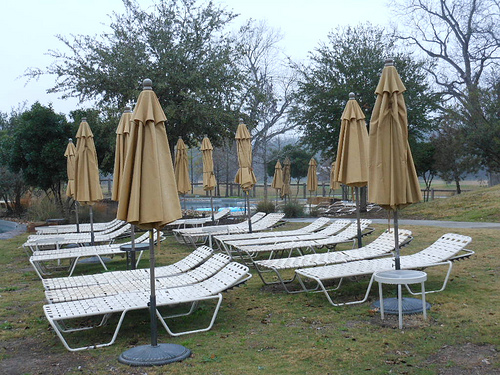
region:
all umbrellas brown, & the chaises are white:
[15, 41, 483, 373]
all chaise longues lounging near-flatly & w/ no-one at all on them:
[25, 204, 481, 331]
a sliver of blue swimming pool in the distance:
[194, 205, 259, 215]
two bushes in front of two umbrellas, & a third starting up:
[249, 199, 326, 219]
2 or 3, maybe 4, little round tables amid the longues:
[117, 223, 429, 332]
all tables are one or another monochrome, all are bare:
[113, 222, 434, 338]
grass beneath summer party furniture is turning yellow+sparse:
[0, 226, 498, 374]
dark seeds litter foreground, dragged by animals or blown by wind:
[0, 263, 498, 374]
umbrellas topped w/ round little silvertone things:
[58, 53, 416, 148]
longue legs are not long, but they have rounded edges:
[20, 205, 471, 360]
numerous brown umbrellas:
[32, 51, 447, 224]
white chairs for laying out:
[34, 203, 477, 330]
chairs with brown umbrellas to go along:
[21, 63, 458, 363]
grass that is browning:
[22, 227, 483, 364]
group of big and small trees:
[3, 13, 495, 215]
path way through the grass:
[221, 205, 492, 236]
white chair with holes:
[46, 281, 252, 321]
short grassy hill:
[365, 176, 498, 233]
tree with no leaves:
[411, 5, 498, 139]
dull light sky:
[11, 0, 493, 131]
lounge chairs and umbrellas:
[23, 54, 468, 361]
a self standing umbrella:
[119, 75, 188, 373]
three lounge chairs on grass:
[25, 242, 255, 356]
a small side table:
[368, 256, 438, 332]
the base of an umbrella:
[118, 332, 197, 370]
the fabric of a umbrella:
[112, 75, 182, 259]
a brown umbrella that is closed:
[115, 67, 183, 242]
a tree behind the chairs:
[45, 2, 281, 146]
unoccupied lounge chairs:
[30, 238, 254, 351]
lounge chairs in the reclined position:
[35, 241, 250, 356]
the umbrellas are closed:
[316, 52, 424, 252]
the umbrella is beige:
[349, 37, 426, 217]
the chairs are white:
[46, 245, 252, 330]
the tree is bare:
[419, 0, 488, 130]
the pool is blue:
[177, 166, 273, 218]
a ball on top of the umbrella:
[135, 75, 155, 92]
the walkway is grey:
[356, 180, 491, 236]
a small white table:
[362, 255, 434, 325]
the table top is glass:
[347, 256, 445, 334]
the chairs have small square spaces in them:
[2, 246, 278, 303]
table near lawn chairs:
[373, 266, 432, 336]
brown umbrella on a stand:
[124, 71, 189, 374]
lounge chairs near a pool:
[217, 226, 479, 301]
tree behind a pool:
[93, 1, 270, 218]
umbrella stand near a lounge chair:
[97, 296, 209, 365]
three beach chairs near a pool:
[29, 246, 255, 343]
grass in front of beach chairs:
[224, 312, 311, 361]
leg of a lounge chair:
[47, 318, 131, 353]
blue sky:
[282, 11, 319, 61]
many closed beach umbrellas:
[19, 51, 292, 241]